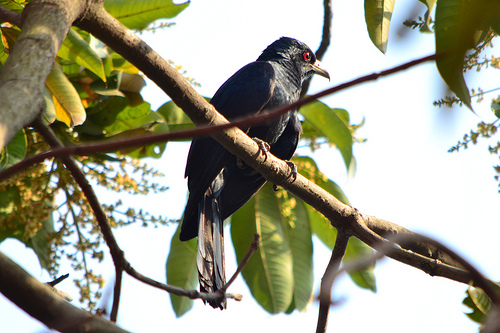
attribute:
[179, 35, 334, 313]
bird — big, colorful, black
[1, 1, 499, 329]
sky — clear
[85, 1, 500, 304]
branch — skinny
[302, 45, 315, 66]
eye — red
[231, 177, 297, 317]
leaf — green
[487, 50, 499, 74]
flower — yellow